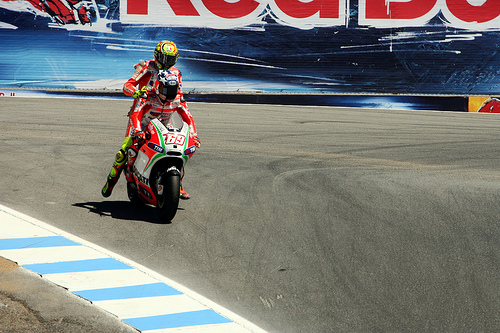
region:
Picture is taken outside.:
[41, 6, 469, 308]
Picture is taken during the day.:
[50, 26, 489, 225]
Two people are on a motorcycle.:
[77, 49, 277, 162]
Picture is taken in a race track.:
[77, 11, 354, 301]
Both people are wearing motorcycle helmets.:
[103, 21, 227, 145]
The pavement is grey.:
[268, 105, 448, 297]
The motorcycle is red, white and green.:
[93, 100, 189, 224]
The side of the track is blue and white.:
[31, 199, 176, 316]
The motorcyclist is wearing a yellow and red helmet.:
[148, 39, 175, 72]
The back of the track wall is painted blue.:
[216, 32, 451, 87]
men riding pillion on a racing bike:
[70, 13, 233, 240]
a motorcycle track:
[43, 17, 495, 227]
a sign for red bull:
[34, 1, 496, 48]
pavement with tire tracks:
[290, 91, 457, 301]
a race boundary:
[20, 211, 181, 331]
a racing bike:
[146, 112, 211, 227]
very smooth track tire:
[162, 172, 190, 221]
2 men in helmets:
[121, 45, 196, 115]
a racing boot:
[95, 150, 136, 207]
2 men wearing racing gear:
[126, 32, 221, 204]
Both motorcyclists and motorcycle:
[92, 30, 220, 252]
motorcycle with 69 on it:
[92, 97, 224, 237]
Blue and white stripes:
[0, 203, 260, 331]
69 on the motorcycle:
[155, 121, 196, 160]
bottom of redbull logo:
[115, 2, 499, 43]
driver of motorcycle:
[129, 75, 206, 164]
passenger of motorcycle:
[125, 44, 205, 149]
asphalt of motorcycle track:
[4, 95, 497, 325]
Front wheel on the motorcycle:
[140, 161, 194, 233]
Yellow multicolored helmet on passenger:
[149, 36, 189, 70]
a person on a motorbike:
[130, 72, 197, 141]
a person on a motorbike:
[99, 39, 184, 191]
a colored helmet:
[151, 70, 179, 100]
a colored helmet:
[153, 37, 182, 64]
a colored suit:
[131, 89, 196, 172]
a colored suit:
[96, 38, 182, 193]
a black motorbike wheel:
[156, 168, 182, 222]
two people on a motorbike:
[101, 37, 201, 227]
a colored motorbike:
[116, 110, 195, 219]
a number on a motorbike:
[164, 127, 187, 146]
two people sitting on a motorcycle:
[86, 26, 241, 243]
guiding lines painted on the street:
[28, 188, 193, 331]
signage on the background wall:
[119, 1, 496, 42]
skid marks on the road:
[275, 118, 470, 300]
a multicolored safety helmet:
[138, 33, 201, 72]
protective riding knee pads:
[76, 104, 168, 239]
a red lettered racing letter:
[148, 124, 206, 171]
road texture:
[289, 111, 460, 202]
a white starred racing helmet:
[151, 69, 189, 93]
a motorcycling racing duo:
[72, 20, 244, 237]